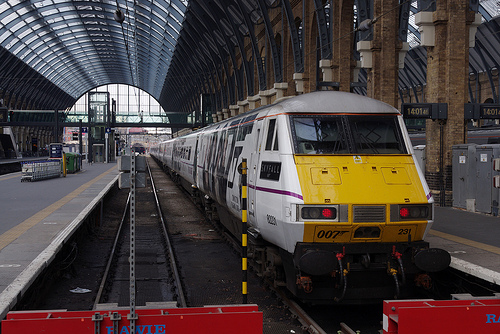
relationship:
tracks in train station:
[90, 156, 189, 311] [1, 1, 498, 332]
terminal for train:
[1, 127, 125, 317] [148, 91, 452, 305]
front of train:
[282, 89, 436, 254] [148, 91, 452, 305]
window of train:
[289, 114, 353, 158] [148, 91, 452, 305]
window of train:
[347, 113, 409, 157] [148, 91, 452, 305]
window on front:
[289, 114, 353, 158] [282, 89, 436, 254]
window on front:
[347, 113, 409, 157] [282, 89, 436, 254]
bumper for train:
[2, 302, 265, 333] [148, 91, 452, 305]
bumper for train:
[383, 292, 499, 333] [148, 91, 452, 305]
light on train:
[302, 207, 336, 219] [148, 91, 452, 305]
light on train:
[399, 206, 430, 221] [148, 91, 452, 305]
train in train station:
[148, 91, 452, 305] [1, 1, 498, 332]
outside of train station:
[62, 84, 172, 157] [1, 1, 498, 332]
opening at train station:
[63, 85, 173, 155] [1, 1, 498, 332]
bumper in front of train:
[2, 302, 265, 333] [148, 91, 452, 305]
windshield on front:
[288, 112, 408, 154] [282, 89, 436, 254]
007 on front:
[316, 230, 341, 240] [282, 89, 436, 254]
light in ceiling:
[113, 9, 126, 22] [1, 0, 424, 122]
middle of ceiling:
[1, 0, 190, 102] [1, 0, 424, 122]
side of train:
[147, 107, 306, 256] [148, 91, 452, 305]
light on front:
[302, 207, 336, 219] [282, 89, 436, 254]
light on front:
[399, 206, 430, 221] [282, 89, 436, 254]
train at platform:
[148, 91, 452, 305] [1, 161, 119, 314]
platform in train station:
[1, 161, 119, 314] [1, 1, 498, 332]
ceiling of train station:
[1, 0, 424, 122] [1, 1, 498, 332]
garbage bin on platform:
[64, 146, 74, 176] [1, 161, 119, 314]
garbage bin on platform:
[76, 145, 81, 172] [1, 161, 119, 314]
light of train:
[302, 207, 336, 219] [148, 91, 452, 305]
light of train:
[399, 206, 430, 221] [148, 91, 452, 305]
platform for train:
[1, 161, 119, 314] [148, 91, 452, 305]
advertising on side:
[192, 111, 257, 210] [147, 107, 306, 256]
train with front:
[148, 91, 452, 305] [282, 89, 436, 254]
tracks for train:
[90, 156, 189, 311] [148, 91, 452, 305]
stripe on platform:
[1, 163, 118, 249] [1, 161, 119, 314]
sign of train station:
[402, 105, 432, 118] [1, 1, 498, 332]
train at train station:
[148, 91, 452, 305] [1, 1, 498, 332]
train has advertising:
[148, 91, 452, 305] [192, 111, 257, 210]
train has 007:
[148, 91, 452, 305] [316, 230, 341, 240]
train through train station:
[148, 91, 452, 305] [1, 1, 498, 332]